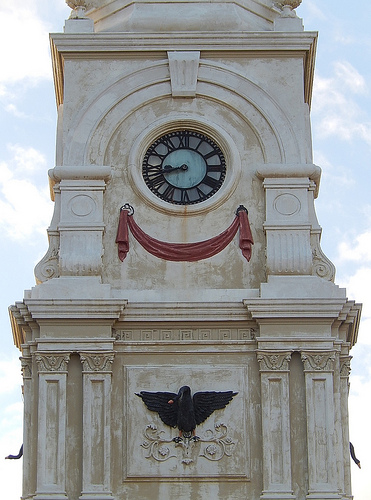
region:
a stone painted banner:
[113, 209, 262, 266]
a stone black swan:
[140, 381, 232, 438]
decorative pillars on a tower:
[252, 350, 348, 497]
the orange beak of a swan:
[167, 395, 176, 405]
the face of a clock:
[144, 122, 227, 193]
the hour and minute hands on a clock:
[151, 161, 192, 180]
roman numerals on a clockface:
[152, 126, 214, 153]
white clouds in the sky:
[337, 58, 362, 141]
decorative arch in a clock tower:
[73, 48, 290, 124]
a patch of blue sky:
[333, 2, 354, 16]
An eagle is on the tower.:
[135, 380, 250, 464]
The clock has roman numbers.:
[139, 128, 228, 217]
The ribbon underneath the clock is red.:
[112, 203, 255, 265]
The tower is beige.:
[33, 284, 369, 373]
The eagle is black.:
[124, 375, 250, 437]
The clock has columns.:
[53, 168, 108, 295]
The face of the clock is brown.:
[142, 141, 233, 201]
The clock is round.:
[138, 116, 230, 201]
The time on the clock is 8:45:
[152, 131, 217, 199]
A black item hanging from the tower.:
[350, 434, 363, 470]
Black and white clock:
[120, 116, 229, 212]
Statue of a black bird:
[129, 377, 225, 428]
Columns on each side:
[259, 351, 343, 488]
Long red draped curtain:
[108, 197, 266, 265]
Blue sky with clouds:
[318, 18, 369, 210]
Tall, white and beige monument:
[48, 73, 349, 488]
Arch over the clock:
[63, 61, 298, 187]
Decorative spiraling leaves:
[134, 422, 242, 470]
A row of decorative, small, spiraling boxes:
[116, 327, 273, 340]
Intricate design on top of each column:
[254, 347, 338, 377]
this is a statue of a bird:
[135, 385, 229, 427]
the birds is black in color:
[166, 403, 197, 422]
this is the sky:
[327, 5, 364, 177]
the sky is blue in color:
[336, 7, 357, 35]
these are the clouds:
[10, 187, 44, 230]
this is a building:
[47, 18, 345, 499]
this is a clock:
[144, 129, 219, 201]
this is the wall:
[74, 53, 304, 149]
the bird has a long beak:
[166, 395, 180, 403]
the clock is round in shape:
[148, 130, 228, 201]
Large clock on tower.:
[140, 133, 275, 237]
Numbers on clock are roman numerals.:
[131, 129, 227, 229]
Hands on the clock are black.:
[131, 170, 257, 213]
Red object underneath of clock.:
[99, 193, 292, 312]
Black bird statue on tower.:
[140, 372, 260, 465]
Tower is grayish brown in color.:
[49, 365, 307, 483]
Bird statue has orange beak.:
[166, 395, 175, 410]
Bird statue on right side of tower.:
[336, 413, 361, 453]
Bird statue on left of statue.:
[6, 417, 42, 481]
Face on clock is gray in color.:
[133, 122, 273, 233]